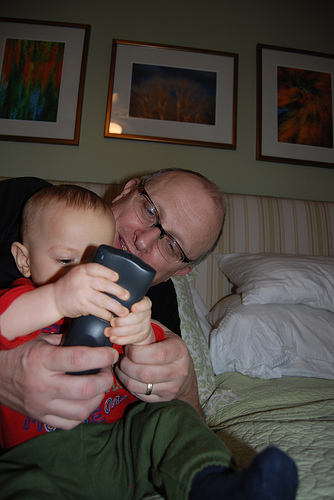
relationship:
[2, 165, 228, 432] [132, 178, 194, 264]
man wearing glasses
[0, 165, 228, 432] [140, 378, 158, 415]
man wearing a ring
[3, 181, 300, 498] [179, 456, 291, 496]
baby wearing socks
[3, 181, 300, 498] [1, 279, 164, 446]
baby wearing a red shirt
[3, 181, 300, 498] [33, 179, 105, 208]
baby with hair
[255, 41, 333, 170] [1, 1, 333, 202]
picture on wall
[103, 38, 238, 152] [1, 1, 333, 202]
picture on wall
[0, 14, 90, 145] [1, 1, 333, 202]
picture on wall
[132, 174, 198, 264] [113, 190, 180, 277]
glasses on face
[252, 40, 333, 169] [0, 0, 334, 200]
frame on pictures wall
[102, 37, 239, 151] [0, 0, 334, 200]
frame on pictures wall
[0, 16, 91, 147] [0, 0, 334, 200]
frame on pictures wall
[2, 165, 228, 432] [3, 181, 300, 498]
man holding baby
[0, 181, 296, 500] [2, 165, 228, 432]
baby in front of man